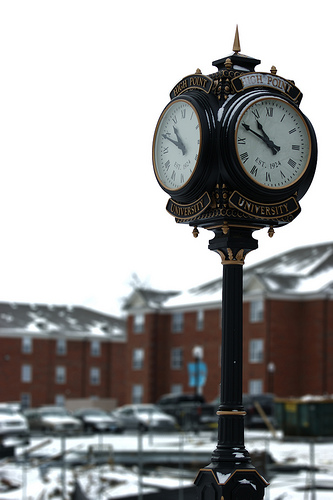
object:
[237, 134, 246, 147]
numerals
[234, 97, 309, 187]
clock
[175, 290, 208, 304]
snow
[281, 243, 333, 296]
roof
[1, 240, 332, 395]
building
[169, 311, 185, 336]
window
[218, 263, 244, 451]
metal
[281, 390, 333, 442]
dumpster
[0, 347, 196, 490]
lot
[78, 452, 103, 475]
tree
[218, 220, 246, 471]
pole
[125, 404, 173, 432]
cars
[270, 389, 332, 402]
lid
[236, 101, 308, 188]
faces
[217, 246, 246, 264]
leaf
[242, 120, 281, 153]
hand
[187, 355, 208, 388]
banner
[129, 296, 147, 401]
third floor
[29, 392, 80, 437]
truck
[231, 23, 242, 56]
point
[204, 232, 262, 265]
bottom